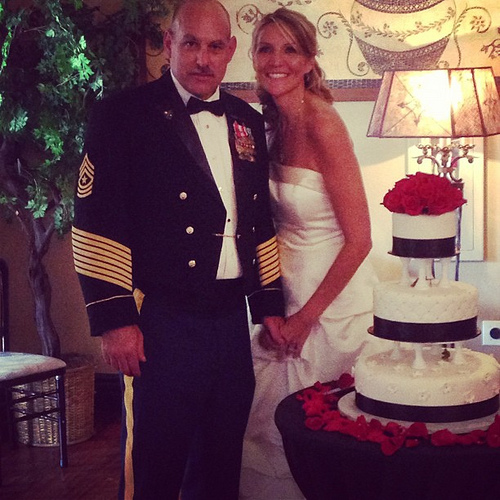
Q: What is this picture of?
A: Wedding.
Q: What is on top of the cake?
A: Red roses.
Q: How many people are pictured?
A: 2.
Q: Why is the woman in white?
A: She is a bride.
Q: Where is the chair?
A: Left.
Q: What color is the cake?
A: Black and white.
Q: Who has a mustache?
A: Man in military uniform.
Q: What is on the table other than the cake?
A: Rose petals.